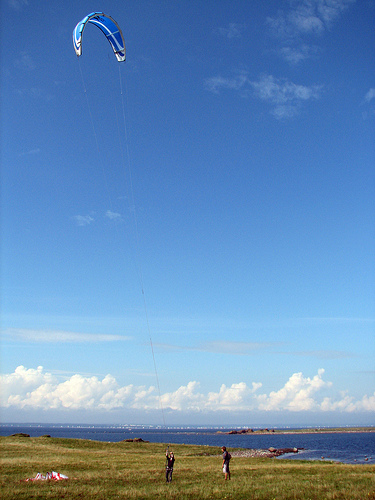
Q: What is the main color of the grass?
A: Green.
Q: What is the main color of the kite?
A: Blue.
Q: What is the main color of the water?
A: Blue.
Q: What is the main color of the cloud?
A: White.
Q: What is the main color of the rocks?
A: Gray.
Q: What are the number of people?
A: 2.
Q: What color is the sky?
A: Blue.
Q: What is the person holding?
A: A line.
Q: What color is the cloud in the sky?
A: White.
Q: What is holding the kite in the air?
A: String.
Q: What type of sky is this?
A: A Brilliant blue sky.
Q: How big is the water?
A: It is large.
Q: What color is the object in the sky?
A: Blue.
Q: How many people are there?
A: 2.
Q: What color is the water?
A: Blue.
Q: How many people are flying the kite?
A: 1.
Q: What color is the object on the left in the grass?
A: Red.